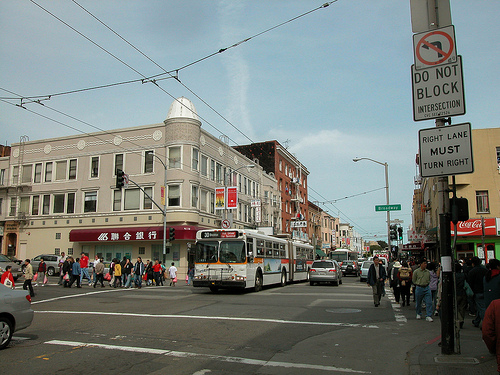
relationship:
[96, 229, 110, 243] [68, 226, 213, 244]
letter on awning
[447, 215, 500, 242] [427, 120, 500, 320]
sign on building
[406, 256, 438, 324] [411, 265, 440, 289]
man wearing shirt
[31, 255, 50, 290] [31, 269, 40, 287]
woman carrying bag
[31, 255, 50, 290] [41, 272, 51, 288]
woman carrying bag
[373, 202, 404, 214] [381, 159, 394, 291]
sign on pole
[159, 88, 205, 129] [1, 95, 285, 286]
dome on building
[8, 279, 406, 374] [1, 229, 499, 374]
lines on street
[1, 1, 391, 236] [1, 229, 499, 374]
power lines above street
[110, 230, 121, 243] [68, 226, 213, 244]
letter on awning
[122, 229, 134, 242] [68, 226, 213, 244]
letter on awning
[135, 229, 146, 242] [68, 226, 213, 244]
letter on awning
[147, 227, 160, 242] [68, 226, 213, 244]
letter on awning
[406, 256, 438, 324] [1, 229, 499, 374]
man crossing street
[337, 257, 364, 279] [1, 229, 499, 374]
car on street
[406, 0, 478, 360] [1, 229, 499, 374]
signs beside street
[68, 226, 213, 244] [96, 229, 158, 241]
awning with writing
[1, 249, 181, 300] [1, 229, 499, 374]
people crossing street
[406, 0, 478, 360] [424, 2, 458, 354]
signs on pole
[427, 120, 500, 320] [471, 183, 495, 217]
building has window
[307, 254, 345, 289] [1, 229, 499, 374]
car on street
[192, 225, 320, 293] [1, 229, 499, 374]
bus on street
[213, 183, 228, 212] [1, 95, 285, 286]
sign on building